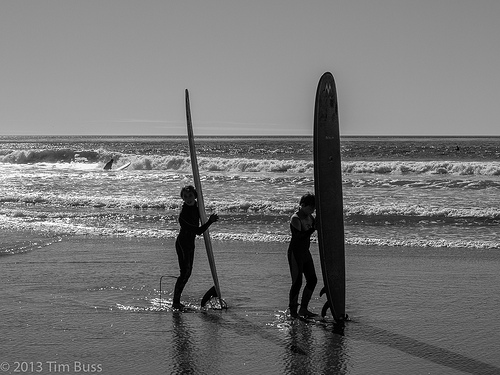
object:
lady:
[286, 193, 320, 319]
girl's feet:
[298, 308, 318, 316]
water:
[1, 229, 164, 271]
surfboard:
[311, 71, 349, 322]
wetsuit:
[172, 202, 210, 310]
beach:
[0, 306, 172, 373]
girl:
[172, 185, 219, 309]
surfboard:
[184, 88, 227, 309]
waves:
[2, 143, 93, 174]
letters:
[74, 360, 82, 372]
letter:
[82, 364, 90, 372]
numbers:
[13, 361, 21, 371]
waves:
[347, 140, 499, 252]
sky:
[1, 1, 500, 136]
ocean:
[0, 137, 175, 241]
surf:
[345, 160, 500, 173]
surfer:
[103, 158, 114, 170]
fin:
[201, 286, 217, 307]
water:
[1, 265, 153, 346]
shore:
[358, 269, 499, 344]